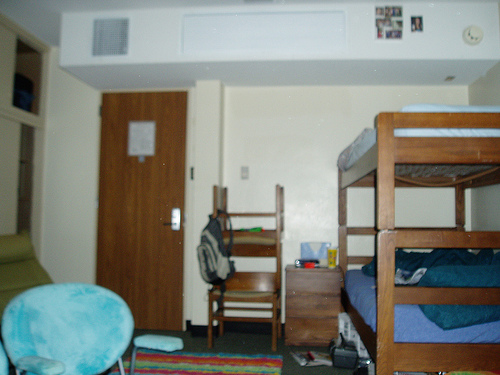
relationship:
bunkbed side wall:
[324, 96, 498, 375] [453, 68, 499, 258]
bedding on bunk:
[343, 260, 498, 341] [324, 96, 498, 375]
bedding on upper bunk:
[325, 98, 494, 150] [321, 98, 499, 205]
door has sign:
[89, 83, 191, 342] [119, 113, 161, 164]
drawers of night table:
[288, 275, 343, 337] [283, 262, 342, 353]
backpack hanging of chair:
[191, 203, 243, 292] [204, 178, 294, 266]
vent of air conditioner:
[87, 13, 132, 56] [87, 16, 140, 59]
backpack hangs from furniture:
[191, 203, 243, 292] [204, 178, 294, 266]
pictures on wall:
[369, 2, 429, 45] [60, 9, 499, 102]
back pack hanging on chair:
[191, 203, 243, 292] [204, 178, 294, 266]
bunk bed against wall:
[324, 96, 498, 375] [453, 68, 499, 258]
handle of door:
[155, 204, 184, 235] [89, 83, 191, 342]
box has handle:
[325, 325, 367, 370] [335, 328, 350, 349]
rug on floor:
[124, 344, 285, 375] [132, 322, 354, 372]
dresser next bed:
[283, 262, 342, 353] [324, 96, 498, 375]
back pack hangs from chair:
[191, 203, 243, 292] [204, 178, 294, 266]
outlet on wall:
[238, 159, 253, 186] [218, 87, 331, 205]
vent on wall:
[87, 13, 132, 56] [60, 9, 499, 102]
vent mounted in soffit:
[87, 13, 132, 56] [55, 10, 197, 85]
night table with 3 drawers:
[283, 262, 342, 353] [288, 275, 343, 337]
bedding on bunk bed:
[343, 278, 498, 341] [337, 276, 496, 374]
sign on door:
[119, 113, 161, 164] [89, 83, 191, 342]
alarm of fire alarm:
[459, 22, 488, 51] [459, 22, 488, 51]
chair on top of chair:
[204, 178, 294, 266] [205, 233, 283, 349]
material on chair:
[29, 291, 109, 352] [3, 275, 142, 374]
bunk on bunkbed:
[321, 98, 499, 205] [324, 96, 498, 375]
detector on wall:
[459, 22, 488, 51] [222, 56, 480, 178]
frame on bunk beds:
[369, 116, 492, 368] [324, 96, 498, 375]